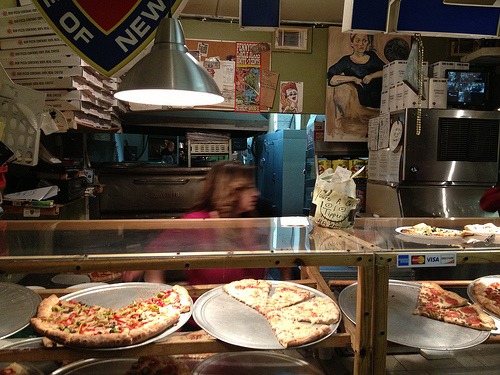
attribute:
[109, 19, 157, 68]
sign — hanging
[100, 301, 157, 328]
pizza — pepperoni, slice, half, displayed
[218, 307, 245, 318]
pan — grey, large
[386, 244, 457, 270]
logos — here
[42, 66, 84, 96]
boxes — empty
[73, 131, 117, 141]
shelf — brown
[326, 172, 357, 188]
bag — paper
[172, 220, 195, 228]
shirt — pink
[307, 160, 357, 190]
trash — decorated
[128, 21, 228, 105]
light — silver, on, metal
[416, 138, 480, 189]
oven — large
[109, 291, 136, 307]
tray — round